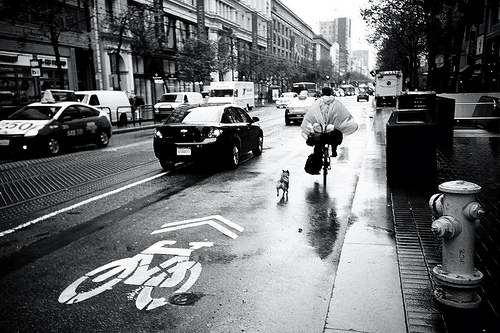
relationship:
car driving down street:
[153, 102, 264, 172] [0, 94, 375, 329]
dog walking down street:
[274, 167, 291, 201] [0, 94, 375, 329]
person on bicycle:
[300, 86, 359, 159] [318, 134, 332, 184]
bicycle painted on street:
[56, 238, 216, 313] [0, 94, 375, 329]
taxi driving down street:
[1, 88, 113, 158] [0, 94, 375, 329]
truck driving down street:
[207, 80, 255, 113] [0, 94, 375, 329]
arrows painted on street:
[150, 212, 244, 242] [0, 94, 375, 329]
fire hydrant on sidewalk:
[426, 179, 487, 310] [391, 124, 499, 332]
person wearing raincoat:
[300, 86, 359, 159] [300, 95, 359, 139]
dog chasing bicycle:
[274, 167, 291, 201] [318, 134, 332, 184]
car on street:
[153, 102, 264, 172] [0, 94, 375, 329]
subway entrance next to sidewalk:
[444, 93, 500, 146] [391, 124, 499, 332]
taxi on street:
[1, 88, 113, 158] [0, 94, 375, 329]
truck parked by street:
[371, 69, 403, 108] [0, 94, 375, 329]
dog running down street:
[274, 167, 291, 201] [0, 94, 375, 329]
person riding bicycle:
[300, 86, 359, 159] [318, 134, 332, 184]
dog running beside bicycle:
[274, 167, 291, 201] [318, 134, 332, 184]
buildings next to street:
[0, 0, 371, 113] [0, 94, 375, 329]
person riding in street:
[300, 86, 359, 159] [0, 94, 375, 329]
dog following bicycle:
[274, 167, 291, 201] [318, 134, 332, 184]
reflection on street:
[302, 179, 341, 261] [0, 94, 375, 329]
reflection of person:
[302, 179, 341, 261] [300, 86, 359, 159]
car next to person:
[153, 102, 264, 172] [300, 86, 359, 159]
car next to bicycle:
[153, 102, 264, 172] [318, 134, 332, 184]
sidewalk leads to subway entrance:
[391, 124, 499, 332] [444, 93, 500, 146]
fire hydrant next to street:
[426, 179, 487, 310] [0, 94, 375, 329]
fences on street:
[101, 102, 174, 134] [0, 94, 375, 329]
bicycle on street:
[56, 238, 216, 313] [0, 94, 375, 329]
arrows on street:
[150, 212, 244, 242] [0, 94, 375, 329]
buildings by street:
[0, 0, 371, 113] [0, 94, 375, 329]